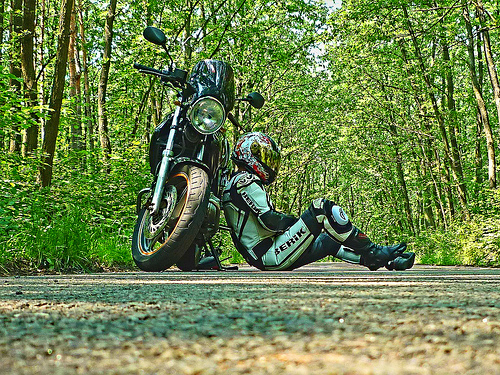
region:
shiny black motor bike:
[119, 21, 271, 284]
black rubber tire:
[128, 160, 210, 276]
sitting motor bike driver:
[214, 122, 425, 279]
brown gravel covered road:
[1, 260, 498, 373]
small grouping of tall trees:
[1, 1, 121, 277]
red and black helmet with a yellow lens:
[232, 125, 290, 188]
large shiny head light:
[179, 90, 229, 137]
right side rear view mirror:
[141, 22, 171, 51]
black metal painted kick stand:
[198, 221, 243, 278]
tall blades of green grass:
[3, 198, 131, 273]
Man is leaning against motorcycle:
[217, 127, 423, 269]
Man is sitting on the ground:
[220, 129, 418, 271]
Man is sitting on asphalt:
[220, 130, 422, 271]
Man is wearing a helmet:
[227, 128, 282, 180]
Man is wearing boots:
[345, 220, 418, 273]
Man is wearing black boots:
[346, 222, 418, 273]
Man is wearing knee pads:
[312, 192, 349, 262]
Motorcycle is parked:
[124, 50, 261, 271]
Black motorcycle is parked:
[131, 19, 261, 276]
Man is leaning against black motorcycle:
[130, 25, 415, 272]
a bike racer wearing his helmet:
[223, 130, 418, 271]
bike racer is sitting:
[223, 129, 414, 271]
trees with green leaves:
[403, 0, 487, 240]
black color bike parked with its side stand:
[131, 26, 237, 273]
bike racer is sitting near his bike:
[130, 23, 416, 273]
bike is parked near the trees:
[66, 25, 233, 268]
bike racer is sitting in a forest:
[100, 23, 485, 268]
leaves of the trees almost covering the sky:
[282, 6, 420, 177]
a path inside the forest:
[3, 183, 491, 350]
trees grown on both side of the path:
[3, 5, 488, 348]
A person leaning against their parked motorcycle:
[105, 20, 429, 277]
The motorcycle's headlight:
[183, 93, 229, 136]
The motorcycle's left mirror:
[238, 87, 266, 110]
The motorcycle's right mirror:
[139, 23, 177, 65]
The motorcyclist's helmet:
[231, 130, 283, 186]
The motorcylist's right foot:
[361, 238, 408, 269]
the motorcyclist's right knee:
[300, 195, 350, 235]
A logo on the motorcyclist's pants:
[270, 225, 307, 257]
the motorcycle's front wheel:
[127, 160, 214, 272]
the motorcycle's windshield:
[178, 55, 240, 113]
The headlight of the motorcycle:
[182, 90, 230, 137]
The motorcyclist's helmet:
[228, 124, 283, 184]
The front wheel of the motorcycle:
[128, 152, 217, 277]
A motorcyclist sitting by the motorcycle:
[217, 123, 422, 273]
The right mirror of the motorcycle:
[141, 20, 176, 65]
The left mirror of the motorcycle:
[232, 85, 268, 111]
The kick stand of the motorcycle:
[201, 228, 239, 272]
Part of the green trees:
[323, 79, 375, 152]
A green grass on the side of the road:
[11, 220, 86, 262]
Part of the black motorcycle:
[192, 67, 221, 92]